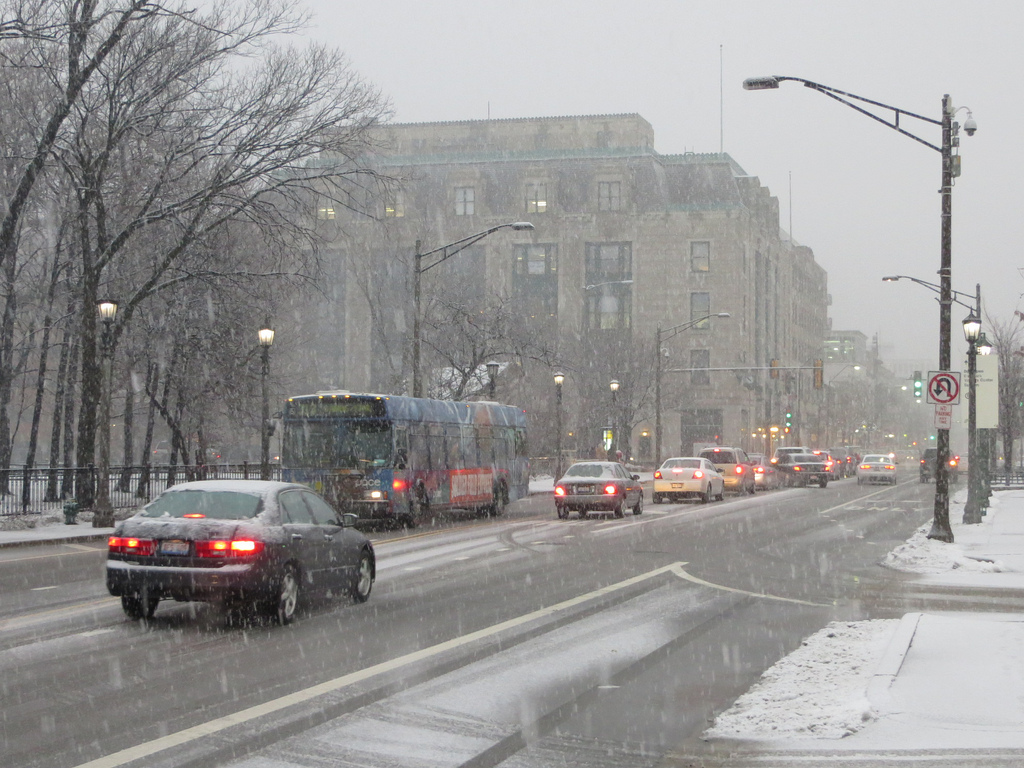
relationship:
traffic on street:
[95, 471, 386, 624] [3, 454, 974, 767]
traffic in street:
[272, 378, 541, 535] [3, 454, 974, 767]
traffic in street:
[548, 450, 645, 521] [3, 454, 974, 767]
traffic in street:
[646, 452, 726, 509] [3, 454, 974, 767]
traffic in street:
[694, 439, 764, 500] [3, 454, 974, 767]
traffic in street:
[744, 451, 788, 490] [3, 454, 974, 767]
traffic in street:
[777, 450, 833, 489] [3, 454, 974, 767]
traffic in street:
[854, 449, 903, 483] [3, 454, 974, 767]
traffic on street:
[272, 378, 541, 535] [3, 454, 974, 767]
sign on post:
[921, 364, 967, 410] [924, 93, 974, 547]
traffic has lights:
[95, 471, 386, 624] [102, 530, 155, 564]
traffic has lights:
[95, 471, 386, 624] [206, 535, 263, 564]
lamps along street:
[736, 66, 786, 97] [3, 454, 974, 767]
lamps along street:
[509, 219, 535, 240] [3, 454, 974, 767]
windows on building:
[581, 234, 642, 338] [225, 95, 837, 489]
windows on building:
[504, 234, 565, 356] [225, 95, 837, 489]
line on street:
[74, 554, 690, 767] [3, 454, 974, 767]